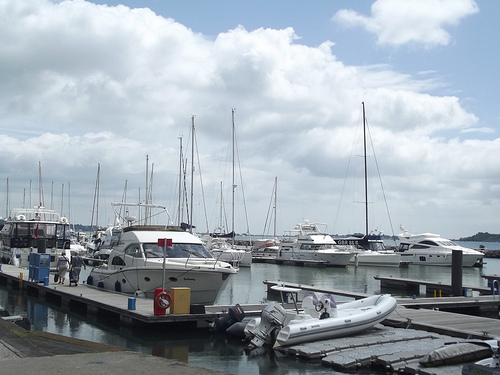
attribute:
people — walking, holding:
[43, 242, 93, 278]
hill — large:
[458, 221, 498, 244]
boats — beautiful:
[77, 213, 271, 297]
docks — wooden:
[77, 286, 159, 325]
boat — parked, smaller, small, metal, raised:
[256, 304, 322, 335]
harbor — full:
[52, 197, 488, 373]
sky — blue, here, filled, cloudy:
[53, 76, 419, 247]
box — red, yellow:
[174, 277, 203, 312]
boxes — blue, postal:
[25, 243, 69, 280]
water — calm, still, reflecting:
[254, 264, 366, 301]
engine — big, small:
[239, 296, 291, 330]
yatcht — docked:
[96, 218, 272, 313]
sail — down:
[101, 189, 156, 227]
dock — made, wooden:
[416, 305, 472, 329]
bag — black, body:
[428, 339, 473, 360]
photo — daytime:
[26, 7, 434, 336]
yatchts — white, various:
[65, 188, 385, 300]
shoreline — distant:
[305, 207, 493, 235]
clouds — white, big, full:
[186, 37, 498, 215]